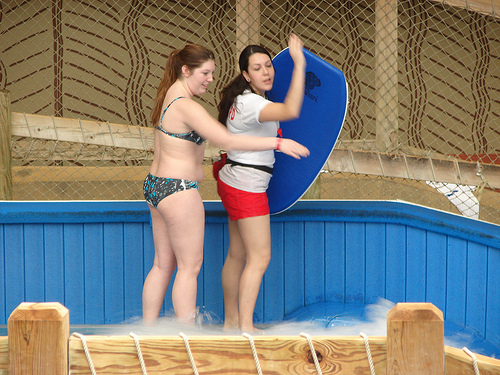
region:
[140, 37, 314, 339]
woman in two piece bathingsuit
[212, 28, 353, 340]
woman wearing red shorts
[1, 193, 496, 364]
blue sides of wading pool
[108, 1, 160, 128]
wavy decorative lines on wall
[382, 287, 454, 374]
light brown wooden posts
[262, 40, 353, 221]
dark blue paddle board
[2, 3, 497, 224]
metal chain link fence behind women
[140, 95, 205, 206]
gray bikini with blue spots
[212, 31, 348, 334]
woman holding a body board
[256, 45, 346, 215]
board is blue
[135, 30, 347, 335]
two women standing in waves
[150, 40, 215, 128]
long golden brown hair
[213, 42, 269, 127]
brunette hair in a pony tail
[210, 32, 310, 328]
lifeguard with a black strap around waist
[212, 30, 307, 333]
woman wearing red shorts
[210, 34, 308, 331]
woman wearing white lifeguard shirt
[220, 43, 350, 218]
The boogie board is blue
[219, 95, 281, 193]
The womans shirt is white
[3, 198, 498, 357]
the wall is blue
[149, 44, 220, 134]
The womans hair is red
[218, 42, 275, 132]
The womans hair is brown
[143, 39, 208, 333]
The woman is wearing a bikini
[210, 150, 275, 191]
The woman has on a fannie pack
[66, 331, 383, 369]
rope around wood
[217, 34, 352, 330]
A woman holding a boogie board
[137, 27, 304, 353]
Two women standing in water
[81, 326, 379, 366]
Several ropes on a board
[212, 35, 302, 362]
A woman wearing orange shorts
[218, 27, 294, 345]
a lady wearing orange shorts and white T-shirt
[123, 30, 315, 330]
Two women standing together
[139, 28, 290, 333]
Two ladies standing together in the water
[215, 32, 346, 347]
a young woman carries a boogie board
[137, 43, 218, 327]
a girl wearing a purple swimsuit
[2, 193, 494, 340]
a blue boundary around a pool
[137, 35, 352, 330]
two girls play at a waterpark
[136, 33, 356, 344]
a couple of women prepare for a ride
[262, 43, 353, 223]
a blue boogie board beign held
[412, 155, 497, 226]
a rip in the fabric of the wall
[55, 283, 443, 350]
water rushing at people's feet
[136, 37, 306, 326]
two girls standing in water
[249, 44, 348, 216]
blue surface of boogie board